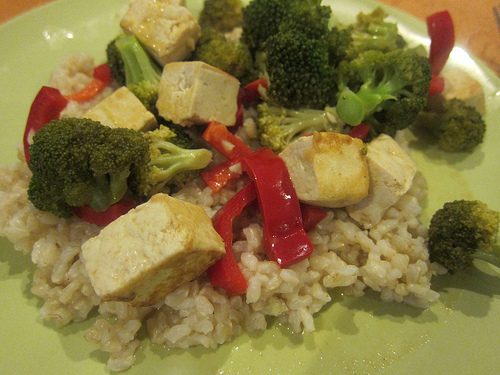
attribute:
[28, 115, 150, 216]
cooked broccoli — dark green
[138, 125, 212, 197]
cooked broccoli — dark green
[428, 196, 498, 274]
cooked broccoli — dark green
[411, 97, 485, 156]
cooked broccoli — dark green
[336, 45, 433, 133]
cooked broccoli — dark green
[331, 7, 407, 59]
cooked broccoli — dark green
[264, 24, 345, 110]
cooked broccoli — dark green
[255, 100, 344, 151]
cooked broccoli — dark green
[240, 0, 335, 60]
cooked broccoli — dark green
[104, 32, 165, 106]
cooked broccoli — dark green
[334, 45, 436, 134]
broccoli — is cooked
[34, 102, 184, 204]
brocolli — small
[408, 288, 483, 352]
plate — is green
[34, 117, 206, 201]
broccoli — green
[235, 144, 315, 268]
red pepper — cooked, strip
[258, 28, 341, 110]
broccoli — green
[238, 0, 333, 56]
broccoli — green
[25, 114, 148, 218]
broccoli — green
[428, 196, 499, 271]
broccoli — green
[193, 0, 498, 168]
brocolli — is cooked, is green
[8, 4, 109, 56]
plate — is round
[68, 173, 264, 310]
tofu — fried, beige, cube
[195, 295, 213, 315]
rice — cooked, white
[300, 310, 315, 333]
rice — white, cooked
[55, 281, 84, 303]
rice — white, cooked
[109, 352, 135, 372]
rice — white, cooked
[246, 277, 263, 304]
rice — white, cooked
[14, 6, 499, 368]
plate — round, green, full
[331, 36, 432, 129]
broccoli — light green, cooked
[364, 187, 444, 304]
rice fried — is fried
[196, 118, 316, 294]
tomato — is red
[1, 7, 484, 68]
table — brown, wood